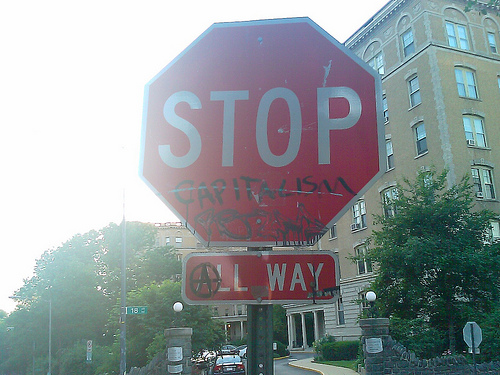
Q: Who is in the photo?
A: No one.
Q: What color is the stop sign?
A: Red.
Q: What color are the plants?
A: Green.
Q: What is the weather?
A: Sunny.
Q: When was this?
A: Daytime.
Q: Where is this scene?
A: Street.